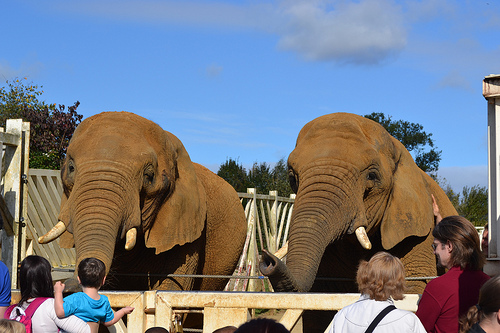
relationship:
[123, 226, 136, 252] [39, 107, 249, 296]
tusk of elephant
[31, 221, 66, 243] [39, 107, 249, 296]
tusk of elephant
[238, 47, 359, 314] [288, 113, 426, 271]
trunk of elephant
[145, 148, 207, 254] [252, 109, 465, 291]
ear of elephant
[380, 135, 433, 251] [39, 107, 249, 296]
ear of elephant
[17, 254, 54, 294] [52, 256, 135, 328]
head of boy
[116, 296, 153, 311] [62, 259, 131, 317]
hand of child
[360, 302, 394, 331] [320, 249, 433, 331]
strap on person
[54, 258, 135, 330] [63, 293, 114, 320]
boy wearing shirt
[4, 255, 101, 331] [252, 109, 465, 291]
momma looking at elephant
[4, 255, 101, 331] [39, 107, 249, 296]
momma looking at elephant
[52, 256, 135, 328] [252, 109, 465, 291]
boy looking at elephant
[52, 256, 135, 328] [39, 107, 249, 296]
boy looking at elephant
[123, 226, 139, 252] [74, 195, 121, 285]
tusk and trunk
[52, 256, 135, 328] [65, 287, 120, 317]
boy wearing shirt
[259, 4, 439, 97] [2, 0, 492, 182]
cloud in sky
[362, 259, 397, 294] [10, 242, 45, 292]
hair on head